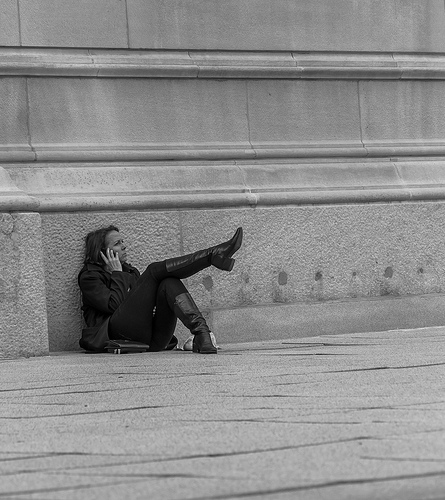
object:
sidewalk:
[1, 363, 442, 497]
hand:
[98, 246, 122, 273]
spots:
[202, 266, 421, 299]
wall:
[254, 0, 442, 275]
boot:
[173, 291, 218, 355]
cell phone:
[98, 247, 117, 262]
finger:
[106, 247, 111, 260]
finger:
[99, 249, 108, 262]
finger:
[115, 251, 119, 257]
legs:
[107, 251, 211, 354]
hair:
[84, 225, 119, 263]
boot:
[164, 226, 242, 279]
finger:
[110, 248, 115, 257]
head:
[85, 225, 126, 266]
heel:
[212, 255, 235, 273]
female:
[77, 225, 243, 355]